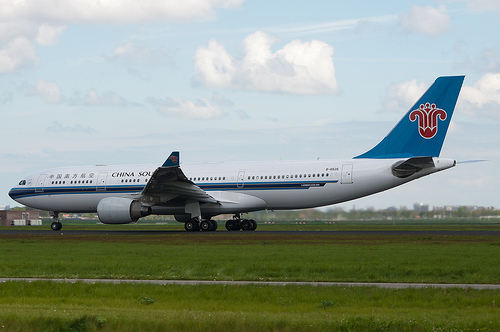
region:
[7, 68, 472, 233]
Airplane with blue wing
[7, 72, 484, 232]
Airplane from China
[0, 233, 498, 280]
Grassy area to the left of the airplane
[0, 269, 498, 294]
Cement sidewalk between two strips of grass+-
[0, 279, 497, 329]
Grassy area to the left of the sidewalk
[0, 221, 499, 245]
Airport runway for the takeoff and landing of planes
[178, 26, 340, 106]
White fluffy cloud in a light blue sky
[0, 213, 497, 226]
Grassy area to the right of the plane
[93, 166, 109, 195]
Door of the airplane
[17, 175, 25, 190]
windshield of the cock pit of the airplane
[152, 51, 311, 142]
part of the blue sky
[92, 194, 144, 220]
left engine of a plane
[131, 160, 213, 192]
left wing of the plane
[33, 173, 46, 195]
front door of the plane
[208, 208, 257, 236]
wheels of the plane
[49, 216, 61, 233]
front wheel of the plane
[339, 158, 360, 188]
rare door of the plane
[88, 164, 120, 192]
second door of the plane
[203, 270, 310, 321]
part of green grass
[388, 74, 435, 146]
part of the tail wing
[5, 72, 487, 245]
a jet is on the runway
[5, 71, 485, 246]
the plane is white and blue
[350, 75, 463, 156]
the tail is blue on the jet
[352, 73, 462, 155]
a red logo is on the blue tail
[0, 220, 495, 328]
green grass surrounds the runway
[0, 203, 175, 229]
buildings are on the horizon near the plane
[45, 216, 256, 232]
black wheels on a jet plane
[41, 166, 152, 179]
black writing on the side of the plane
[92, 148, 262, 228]
a jet engine on the plane's wing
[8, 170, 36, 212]
the jet has windows in the cockpit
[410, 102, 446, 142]
A red and white emblem.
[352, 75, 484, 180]
The tail end of airplane.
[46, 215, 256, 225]
The wheels of the airplane.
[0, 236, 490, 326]
The grassy area around airplane.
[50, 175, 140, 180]
The windows of the plane.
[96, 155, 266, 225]
The wing of the plane.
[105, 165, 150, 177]
The "China Sol" title.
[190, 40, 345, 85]
The white cloud in sky.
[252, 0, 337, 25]
The baby blue sky.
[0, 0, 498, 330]
An airplane sitting on the tarmac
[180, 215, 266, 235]
landing gear on plane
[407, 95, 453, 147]
red design on blue tail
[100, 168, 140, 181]
word china on plane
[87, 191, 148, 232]
jet engine on side of plane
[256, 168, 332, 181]
windows for plane passengers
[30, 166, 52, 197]
door near front of plane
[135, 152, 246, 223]
wing on side of plane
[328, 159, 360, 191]
door on back of plane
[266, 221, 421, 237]
airport runway under plane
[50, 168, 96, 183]
Chinese characters in black